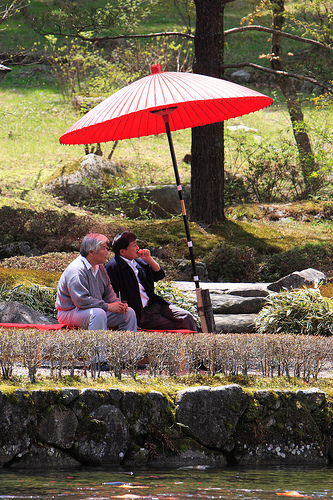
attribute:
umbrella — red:
[54, 54, 283, 333]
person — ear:
[49, 226, 140, 332]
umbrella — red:
[54, 58, 273, 148]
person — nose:
[59, 227, 137, 340]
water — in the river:
[171, 478, 228, 497]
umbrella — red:
[59, 63, 272, 144]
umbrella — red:
[53, 40, 277, 170]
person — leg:
[54, 227, 131, 331]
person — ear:
[65, 234, 121, 325]